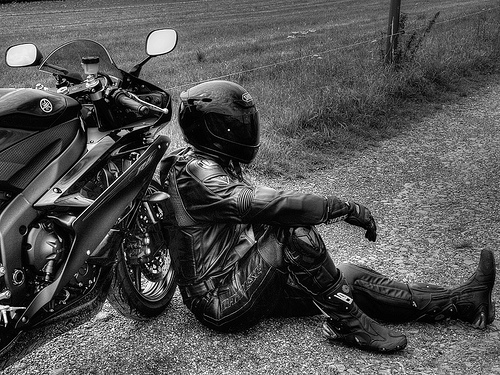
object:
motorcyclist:
[154, 78, 496, 357]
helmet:
[174, 79, 264, 168]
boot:
[350, 246, 498, 329]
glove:
[322, 193, 378, 243]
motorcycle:
[0, 28, 181, 360]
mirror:
[145, 27, 179, 57]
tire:
[104, 179, 179, 325]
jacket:
[154, 148, 328, 304]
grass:
[160, 16, 500, 183]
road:
[0, 83, 500, 375]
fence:
[0, 0, 500, 92]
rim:
[121, 187, 176, 303]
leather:
[186, 176, 224, 215]